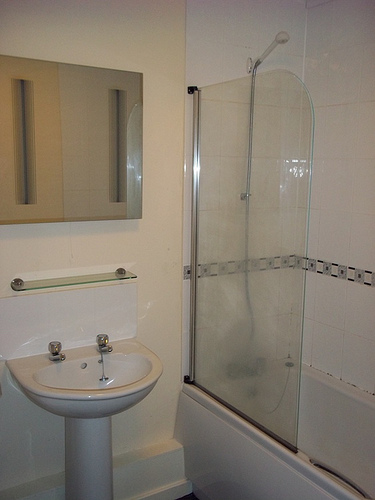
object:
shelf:
[8, 265, 138, 292]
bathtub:
[175, 352, 375, 498]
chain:
[251, 368, 291, 414]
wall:
[1, 15, 185, 493]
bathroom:
[2, 1, 368, 491]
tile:
[302, 33, 373, 106]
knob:
[48, 340, 62, 354]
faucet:
[94, 333, 116, 356]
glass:
[0, 53, 144, 225]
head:
[253, 22, 295, 69]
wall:
[188, 0, 374, 401]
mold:
[179, 344, 374, 437]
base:
[293, 358, 375, 500]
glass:
[183, 67, 326, 452]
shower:
[171, 11, 371, 498]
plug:
[284, 359, 294, 368]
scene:
[0, 0, 372, 498]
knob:
[96, 334, 110, 345]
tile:
[320, 257, 333, 276]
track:
[172, 375, 374, 497]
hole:
[80, 362, 87, 369]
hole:
[97, 359, 103, 364]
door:
[1, 53, 68, 226]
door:
[58, 59, 143, 220]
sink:
[5, 335, 164, 420]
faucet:
[47, 341, 66, 362]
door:
[188, 67, 312, 454]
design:
[322, 261, 332, 276]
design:
[307, 258, 317, 271]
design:
[281, 255, 290, 270]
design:
[235, 259, 245, 275]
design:
[183, 264, 193, 281]